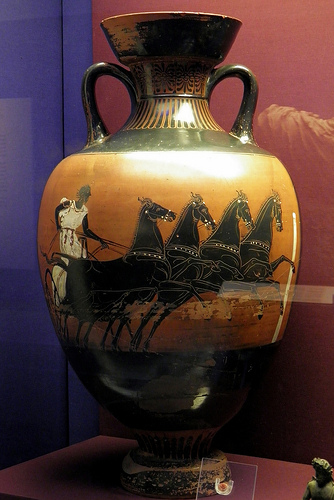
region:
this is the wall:
[11, 400, 54, 422]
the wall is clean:
[15, 389, 61, 437]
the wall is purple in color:
[20, 393, 52, 433]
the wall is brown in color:
[272, 10, 314, 64]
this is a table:
[23, 458, 71, 489]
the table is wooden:
[24, 460, 58, 491]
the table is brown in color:
[274, 469, 296, 496]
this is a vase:
[51, 12, 295, 480]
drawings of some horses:
[117, 191, 298, 318]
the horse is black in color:
[103, 262, 135, 281]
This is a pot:
[49, 0, 322, 497]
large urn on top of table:
[38, 13, 284, 435]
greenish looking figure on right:
[307, 437, 333, 491]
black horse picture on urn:
[131, 188, 182, 245]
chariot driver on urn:
[54, 179, 104, 260]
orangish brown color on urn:
[191, 313, 238, 341]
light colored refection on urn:
[179, 376, 244, 417]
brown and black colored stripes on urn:
[151, 94, 202, 133]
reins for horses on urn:
[98, 232, 128, 267]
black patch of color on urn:
[231, 363, 260, 392]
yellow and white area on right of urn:
[210, 471, 253, 496]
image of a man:
[53, 188, 107, 299]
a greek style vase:
[36, 11, 301, 495]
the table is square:
[0, 434, 333, 498]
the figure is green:
[300, 457, 333, 498]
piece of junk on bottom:
[213, 477, 233, 495]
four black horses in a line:
[40, 189, 297, 350]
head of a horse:
[139, 196, 174, 221]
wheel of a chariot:
[41, 267, 63, 335]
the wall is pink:
[91, 0, 332, 465]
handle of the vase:
[207, 63, 257, 144]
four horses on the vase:
[129, 191, 288, 280]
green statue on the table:
[312, 459, 326, 498]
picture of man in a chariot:
[55, 179, 111, 323]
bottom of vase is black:
[70, 352, 237, 418]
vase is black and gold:
[37, 21, 272, 487]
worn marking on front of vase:
[142, 357, 215, 409]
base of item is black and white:
[122, 463, 214, 494]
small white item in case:
[204, 476, 240, 495]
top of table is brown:
[11, 456, 125, 499]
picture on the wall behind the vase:
[268, 98, 332, 163]